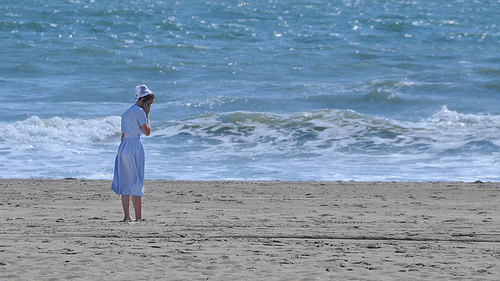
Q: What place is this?
A: It is an ocean.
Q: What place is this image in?
A: It is at the ocean.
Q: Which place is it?
A: It is an ocean.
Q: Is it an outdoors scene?
A: Yes, it is outdoors.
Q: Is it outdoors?
A: Yes, it is outdoors.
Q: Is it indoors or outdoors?
A: It is outdoors.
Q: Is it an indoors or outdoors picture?
A: It is outdoors.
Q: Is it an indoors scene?
A: No, it is outdoors.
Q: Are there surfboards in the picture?
A: No, there are no surfboards.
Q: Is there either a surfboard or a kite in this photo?
A: No, there are no surfboards or kites.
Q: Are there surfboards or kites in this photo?
A: No, there are no surfboards or kites.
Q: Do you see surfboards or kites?
A: No, there are no surfboards or kites.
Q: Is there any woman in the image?
A: Yes, there is a woman.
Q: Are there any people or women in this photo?
A: Yes, there is a woman.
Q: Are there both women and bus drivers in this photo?
A: No, there is a woman but no bus drivers.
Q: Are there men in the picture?
A: No, there are no men.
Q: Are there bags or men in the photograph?
A: No, there are no men or bags.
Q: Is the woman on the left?
A: Yes, the woman is on the left of the image.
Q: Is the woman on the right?
A: No, the woman is on the left of the image.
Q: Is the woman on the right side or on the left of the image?
A: The woman is on the left of the image.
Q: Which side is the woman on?
A: The woman is on the left of the image.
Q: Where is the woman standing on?
A: The woman is standing on the beach.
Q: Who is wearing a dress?
A: The woman is wearing a dress.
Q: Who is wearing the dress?
A: The woman is wearing a dress.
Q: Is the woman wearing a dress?
A: Yes, the woman is wearing a dress.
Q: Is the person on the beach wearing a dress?
A: Yes, the woman is wearing a dress.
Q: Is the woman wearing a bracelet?
A: No, the woman is wearing a dress.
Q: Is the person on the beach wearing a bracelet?
A: No, the woman is wearing a dress.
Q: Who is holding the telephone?
A: The woman is holding the telephone.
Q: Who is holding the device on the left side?
A: The woman is holding the telephone.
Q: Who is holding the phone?
A: The woman is holding the telephone.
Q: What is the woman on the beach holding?
A: The woman is holding the phone.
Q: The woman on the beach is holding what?
A: The woman is holding the phone.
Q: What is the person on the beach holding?
A: The woman is holding the phone.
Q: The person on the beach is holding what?
A: The woman is holding the phone.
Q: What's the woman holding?
A: The woman is holding the phone.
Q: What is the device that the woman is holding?
A: The device is a phone.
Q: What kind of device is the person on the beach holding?
A: The woman is holding the telephone.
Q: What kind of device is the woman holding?
A: The woman is holding the telephone.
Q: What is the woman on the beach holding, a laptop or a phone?
A: The woman is holding a phone.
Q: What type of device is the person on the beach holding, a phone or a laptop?
A: The woman is holding a phone.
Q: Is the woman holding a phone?
A: Yes, the woman is holding a phone.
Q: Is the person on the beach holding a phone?
A: Yes, the woman is holding a phone.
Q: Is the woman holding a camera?
A: No, the woman is holding a phone.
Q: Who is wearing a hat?
A: The woman is wearing a hat.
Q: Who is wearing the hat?
A: The woman is wearing a hat.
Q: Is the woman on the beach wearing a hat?
A: Yes, the woman is wearing a hat.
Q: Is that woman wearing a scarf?
A: No, the woman is wearing a hat.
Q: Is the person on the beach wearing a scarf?
A: No, the woman is wearing a hat.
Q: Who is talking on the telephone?
A: The woman is talking on the telephone.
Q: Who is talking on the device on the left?
A: The woman is talking on the telephone.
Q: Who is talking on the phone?
A: The woman is talking on the telephone.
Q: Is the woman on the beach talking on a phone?
A: Yes, the woman is talking on a phone.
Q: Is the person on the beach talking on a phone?
A: Yes, the woman is talking on a phone.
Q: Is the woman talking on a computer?
A: No, the woman is talking on a phone.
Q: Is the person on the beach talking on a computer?
A: No, the woman is talking on a phone.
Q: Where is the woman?
A: The woman is on the beach.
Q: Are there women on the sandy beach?
A: Yes, there is a woman on the beach.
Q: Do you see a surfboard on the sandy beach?
A: No, there is a woman on the beach.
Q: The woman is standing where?
A: The woman is standing at the beach.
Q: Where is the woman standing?
A: The woman is standing at the beach.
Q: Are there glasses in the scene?
A: No, there are no glasses.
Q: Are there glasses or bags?
A: No, there are no glasses or bags.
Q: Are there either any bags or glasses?
A: No, there are no glasses or bags.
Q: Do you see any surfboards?
A: No, there are no surfboards.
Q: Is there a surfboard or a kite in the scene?
A: No, there are no surfboards or kites.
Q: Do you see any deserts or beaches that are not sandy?
A: No, there is a beach but it is sandy.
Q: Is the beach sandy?
A: Yes, the beach is sandy.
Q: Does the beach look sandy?
A: Yes, the beach is sandy.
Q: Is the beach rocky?
A: No, the beach is sandy.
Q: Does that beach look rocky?
A: No, the beach is sandy.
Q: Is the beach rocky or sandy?
A: The beach is sandy.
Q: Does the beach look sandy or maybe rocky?
A: The beach is sandy.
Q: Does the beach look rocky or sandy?
A: The beach is sandy.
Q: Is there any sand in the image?
A: Yes, there is sand.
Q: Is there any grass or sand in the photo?
A: Yes, there is sand.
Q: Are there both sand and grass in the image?
A: No, there is sand but no grass.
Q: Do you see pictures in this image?
A: No, there are no pictures.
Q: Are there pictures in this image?
A: No, there are no pictures.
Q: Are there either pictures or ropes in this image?
A: No, there are no pictures or ropes.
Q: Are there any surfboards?
A: No, there are no surfboards.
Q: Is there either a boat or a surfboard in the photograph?
A: No, there are no surfboards or boats.